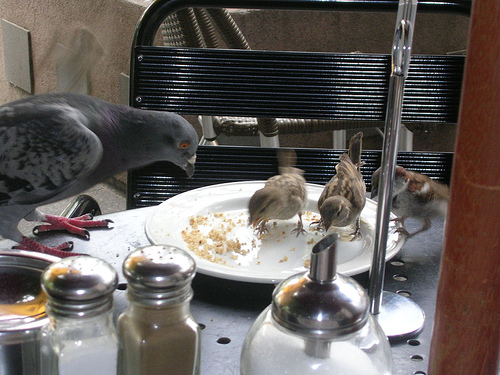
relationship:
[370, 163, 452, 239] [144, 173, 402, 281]
bird on plate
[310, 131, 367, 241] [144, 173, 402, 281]
birds on plate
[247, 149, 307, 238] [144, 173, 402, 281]
bird on plate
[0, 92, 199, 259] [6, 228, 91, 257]
bird has foot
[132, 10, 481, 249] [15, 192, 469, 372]
chair at table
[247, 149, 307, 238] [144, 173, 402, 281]
bird standing in plate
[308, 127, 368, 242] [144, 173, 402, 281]
birds standing in plate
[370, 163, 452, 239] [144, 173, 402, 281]
bird standing in plate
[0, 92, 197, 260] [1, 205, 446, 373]
bird sitting in table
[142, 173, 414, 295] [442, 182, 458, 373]
plate on table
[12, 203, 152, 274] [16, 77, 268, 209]
toes on bird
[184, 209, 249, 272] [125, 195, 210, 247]
crumbs on plate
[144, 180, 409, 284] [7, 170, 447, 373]
plate on table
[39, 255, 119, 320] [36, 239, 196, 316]
lids with lids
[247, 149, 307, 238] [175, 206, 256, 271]
bird eating crumbs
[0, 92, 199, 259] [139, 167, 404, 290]
bird standing on edge of plate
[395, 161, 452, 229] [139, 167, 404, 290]
bird standing on edge of plate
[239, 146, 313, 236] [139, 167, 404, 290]
bird standing on edge of plate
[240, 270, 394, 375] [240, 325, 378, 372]
bottle of sugar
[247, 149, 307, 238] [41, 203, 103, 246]
bird with foot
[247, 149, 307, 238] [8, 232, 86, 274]
bird with foot